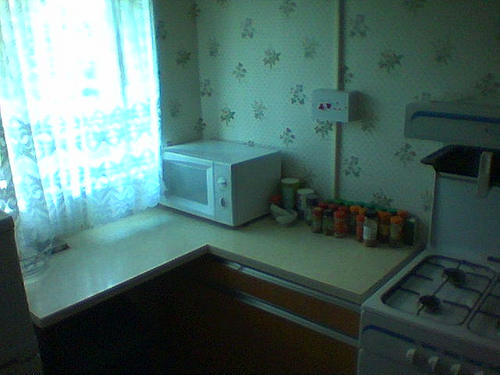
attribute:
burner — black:
[378, 250, 497, 330]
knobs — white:
[213, 176, 229, 212]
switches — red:
[317, 102, 332, 110]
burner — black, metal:
[380, 253, 490, 330]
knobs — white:
[405, 348, 467, 374]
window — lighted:
[0, 5, 150, 204]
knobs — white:
[399, 343, 486, 374]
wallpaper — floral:
[201, 41, 373, 169]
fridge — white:
[5, 201, 67, 358]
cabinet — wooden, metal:
[239, 264, 368, 347]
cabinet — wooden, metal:
[227, 287, 362, 373]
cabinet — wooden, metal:
[151, 274, 233, 374]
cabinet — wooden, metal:
[175, 255, 241, 300]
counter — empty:
[18, 197, 425, 327]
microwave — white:
[156, 138, 281, 230]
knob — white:
[404, 347, 417, 364]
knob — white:
[427, 355, 439, 371]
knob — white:
[446, 362, 463, 372]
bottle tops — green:
[363, 209, 380, 219]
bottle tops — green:
[388, 206, 399, 216]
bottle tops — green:
[361, 201, 375, 211]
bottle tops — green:
[343, 199, 354, 208]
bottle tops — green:
[332, 195, 344, 205]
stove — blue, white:
[350, 143, 499, 373]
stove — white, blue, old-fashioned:
[356, 97, 498, 373]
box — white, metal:
[296, 82, 373, 132]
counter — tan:
[47, 187, 494, 332]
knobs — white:
[399, 346, 459, 364]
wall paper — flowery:
[218, 60, 385, 153]